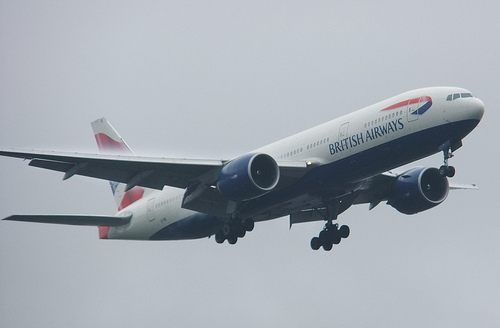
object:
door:
[406, 97, 421, 122]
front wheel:
[439, 165, 456, 178]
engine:
[217, 152, 281, 203]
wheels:
[311, 222, 350, 251]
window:
[446, 94, 452, 102]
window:
[453, 93, 461, 101]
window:
[461, 92, 473, 97]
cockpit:
[444, 91, 484, 120]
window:
[378, 117, 381, 123]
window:
[399, 109, 403, 115]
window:
[316, 141, 319, 147]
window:
[327, 137, 330, 142]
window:
[306, 145, 309, 150]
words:
[328, 116, 405, 155]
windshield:
[446, 93, 473, 102]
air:
[0, 0, 500, 327]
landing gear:
[213, 137, 463, 251]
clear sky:
[0, 2, 498, 327]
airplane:
[0, 87, 485, 251]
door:
[336, 122, 349, 142]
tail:
[89, 117, 153, 213]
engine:
[389, 166, 450, 215]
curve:
[380, 96, 433, 116]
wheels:
[214, 217, 255, 245]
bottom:
[218, 152, 450, 216]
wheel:
[309, 237, 332, 252]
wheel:
[340, 224, 350, 238]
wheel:
[332, 232, 342, 244]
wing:
[0, 148, 321, 194]